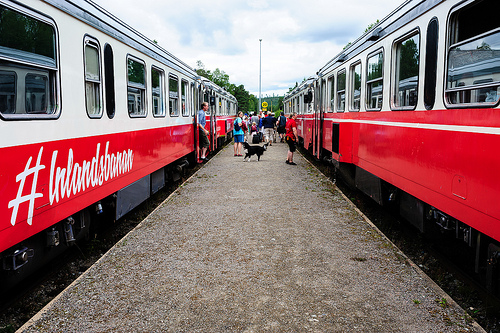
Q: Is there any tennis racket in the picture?
A: No, there are no rackets.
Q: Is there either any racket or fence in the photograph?
A: No, there are no rackets or fences.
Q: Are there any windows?
A: Yes, there is a window.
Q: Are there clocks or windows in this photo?
A: Yes, there is a window.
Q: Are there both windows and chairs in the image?
A: No, there is a window but no chairs.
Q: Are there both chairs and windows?
A: No, there is a window but no chairs.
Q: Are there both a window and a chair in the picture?
A: No, there is a window but no chairs.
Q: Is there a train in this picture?
A: Yes, there is a train.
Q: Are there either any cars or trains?
A: Yes, there is a train.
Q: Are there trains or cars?
A: Yes, there is a train.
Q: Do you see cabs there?
A: No, there are no cabs.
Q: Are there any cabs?
A: No, there are no cabs.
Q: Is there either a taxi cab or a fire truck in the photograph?
A: No, there are no taxis or fire trucks.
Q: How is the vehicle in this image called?
A: The vehicle is a train.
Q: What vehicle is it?
A: The vehicle is a train.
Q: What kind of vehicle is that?
A: This is a train.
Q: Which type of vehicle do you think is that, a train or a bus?
A: This is a train.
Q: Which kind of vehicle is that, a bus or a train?
A: This is a train.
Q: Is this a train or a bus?
A: This is a train.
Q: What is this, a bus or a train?
A: This is a train.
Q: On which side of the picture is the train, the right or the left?
A: The train is on the left of the image.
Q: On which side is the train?
A: The train is on the left of the image.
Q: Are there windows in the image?
A: Yes, there is a window.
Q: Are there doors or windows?
A: Yes, there is a window.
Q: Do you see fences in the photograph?
A: No, there are no fences.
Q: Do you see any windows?
A: Yes, there is a window.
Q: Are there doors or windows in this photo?
A: Yes, there is a window.